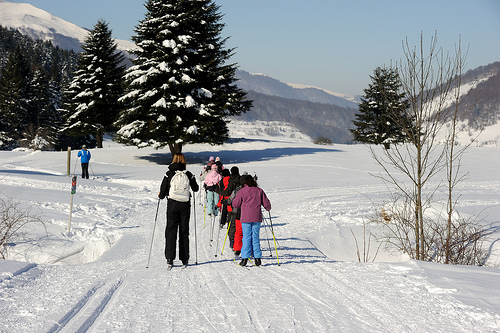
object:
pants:
[164, 197, 192, 263]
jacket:
[156, 165, 199, 201]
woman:
[158, 153, 199, 264]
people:
[200, 156, 272, 266]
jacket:
[77, 149, 91, 165]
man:
[77, 145, 91, 179]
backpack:
[169, 170, 193, 204]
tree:
[349, 66, 424, 149]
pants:
[240, 221, 262, 259]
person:
[232, 175, 273, 266]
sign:
[71, 176, 78, 195]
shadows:
[258, 216, 338, 267]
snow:
[324, 260, 497, 332]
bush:
[367, 32, 484, 266]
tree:
[112, 1, 255, 163]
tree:
[65, 20, 129, 148]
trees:
[1, 25, 61, 151]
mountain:
[0, 1, 499, 145]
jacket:
[231, 184, 272, 223]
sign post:
[68, 193, 74, 231]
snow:
[2, 271, 365, 333]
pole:
[65, 146, 73, 179]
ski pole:
[145, 197, 161, 268]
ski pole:
[192, 192, 199, 265]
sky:
[15, 1, 499, 105]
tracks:
[46, 275, 124, 332]